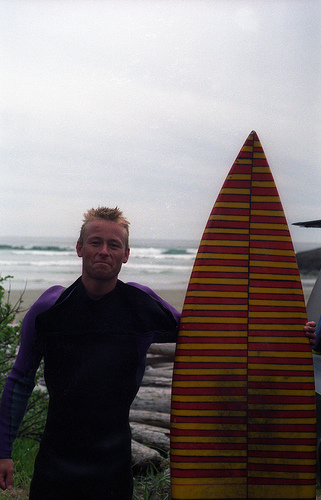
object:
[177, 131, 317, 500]
surfboard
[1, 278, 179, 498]
wetsuit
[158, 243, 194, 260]
rocks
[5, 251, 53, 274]
waves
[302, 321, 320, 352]
hand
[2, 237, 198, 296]
ocean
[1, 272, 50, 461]
shrubbery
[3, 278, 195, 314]
sand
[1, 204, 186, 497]
man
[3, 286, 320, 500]
beach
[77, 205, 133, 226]
hair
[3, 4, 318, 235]
sky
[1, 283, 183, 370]
shore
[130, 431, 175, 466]
wood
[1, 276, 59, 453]
sleeve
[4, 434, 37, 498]
grass